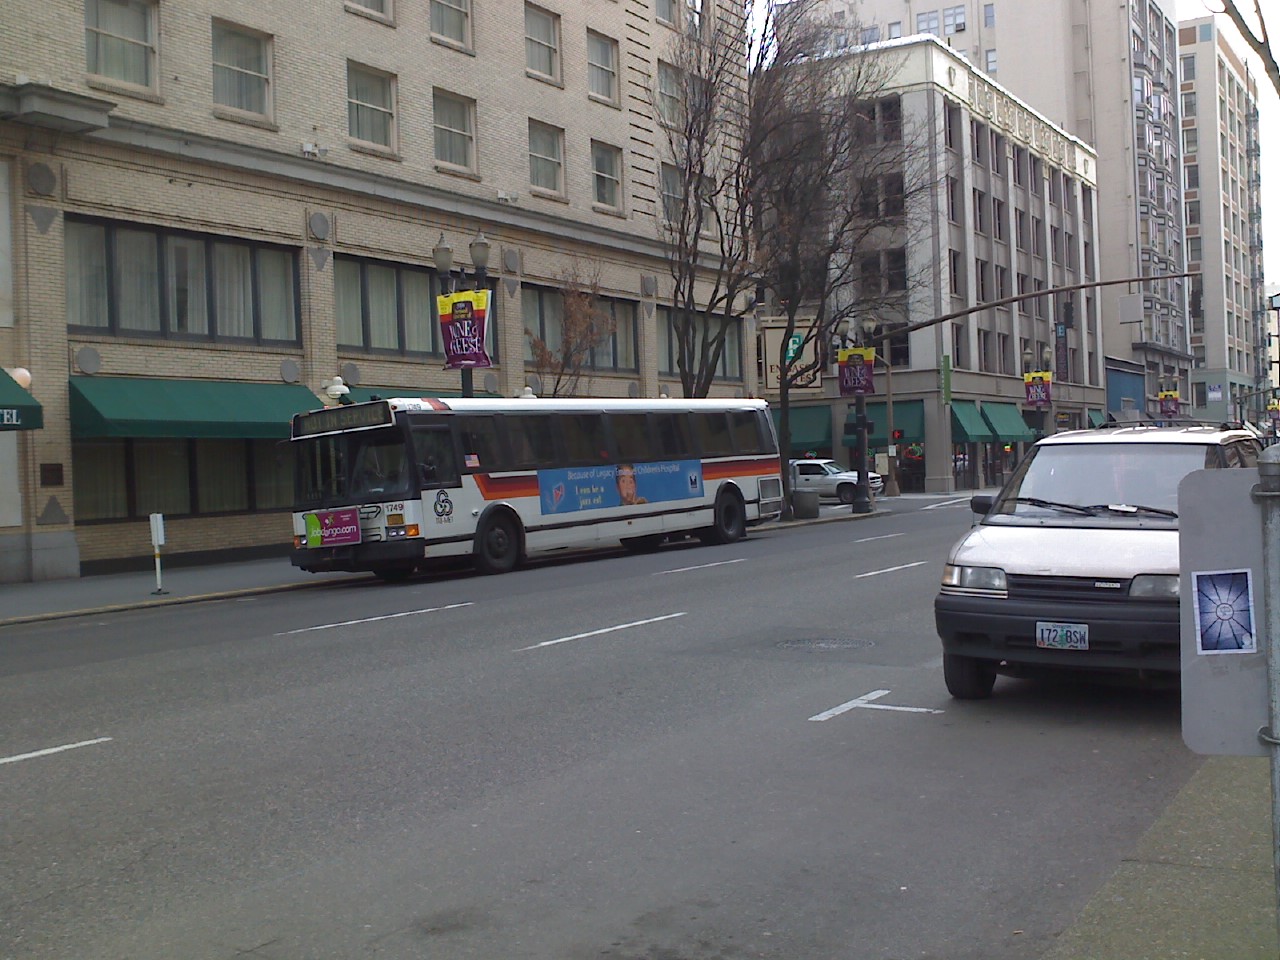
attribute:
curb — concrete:
[29, 559, 345, 614]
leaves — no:
[655, 19, 878, 351]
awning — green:
[73, 371, 329, 454]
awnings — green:
[950, 396, 1036, 454]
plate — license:
[1030, 613, 1104, 668]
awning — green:
[978, 391, 1036, 449]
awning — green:
[950, 394, 996, 449]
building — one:
[18, 11, 781, 569]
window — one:
[97, 207, 185, 346]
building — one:
[34, 35, 822, 570]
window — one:
[153, 209, 229, 348]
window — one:
[206, 237, 271, 348]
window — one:
[250, 228, 317, 369]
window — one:
[325, 223, 373, 341]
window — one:
[604, 284, 662, 395]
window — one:
[863, 76, 921, 143]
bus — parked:
[276, 363, 801, 591]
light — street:
[430, 223, 516, 388]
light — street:
[835, 258, 1121, 472]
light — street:
[1004, 332, 1080, 432]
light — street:
[1095, 332, 1176, 415]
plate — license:
[1025, 612, 1106, 656]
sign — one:
[1172, 453, 1262, 809]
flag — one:
[432, 439, 494, 508]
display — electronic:
[271, 395, 408, 450]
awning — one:
[39, 360, 327, 492]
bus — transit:
[297, 346, 774, 557]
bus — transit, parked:
[285, 377, 806, 579]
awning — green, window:
[80, 335, 361, 469]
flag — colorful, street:
[415, 272, 517, 379]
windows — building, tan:
[578, 139, 622, 215]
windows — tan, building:
[536, 116, 568, 188]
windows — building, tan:
[426, 79, 500, 176]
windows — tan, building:
[345, 65, 398, 144]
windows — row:
[459, 416, 591, 469]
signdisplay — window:
[417, 274, 491, 367]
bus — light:
[282, 346, 777, 613]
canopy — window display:
[70, 353, 330, 464]